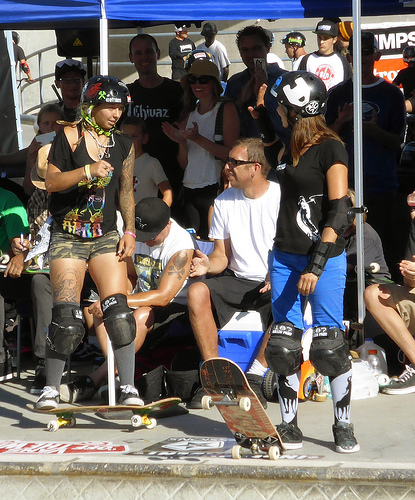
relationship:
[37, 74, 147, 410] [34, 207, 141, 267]
she wearing shorts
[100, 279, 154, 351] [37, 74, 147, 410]
knee pad on knees of she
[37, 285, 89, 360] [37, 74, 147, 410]
knee pad on knees of she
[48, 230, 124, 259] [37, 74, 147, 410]
camo shorts on she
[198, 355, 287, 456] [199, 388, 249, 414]
skateboard with wheels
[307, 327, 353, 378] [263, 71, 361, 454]
kneepad on girl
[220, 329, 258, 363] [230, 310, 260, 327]
cooler has white lid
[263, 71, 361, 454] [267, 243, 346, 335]
girl wearing pants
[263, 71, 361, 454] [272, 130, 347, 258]
girl wearing shirt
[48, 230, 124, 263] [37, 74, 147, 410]
camo shorts on a she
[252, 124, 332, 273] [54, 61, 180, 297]
shirt on woman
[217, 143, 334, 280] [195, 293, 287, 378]
he on cooler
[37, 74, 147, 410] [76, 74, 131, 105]
she wearing helmet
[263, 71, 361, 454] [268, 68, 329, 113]
girl wearing helmet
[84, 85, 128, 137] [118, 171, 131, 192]
she has tattoos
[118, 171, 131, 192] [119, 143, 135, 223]
tattoos on arm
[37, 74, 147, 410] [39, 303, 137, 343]
she wearing knee pads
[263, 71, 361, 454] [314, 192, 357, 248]
girl wearing pads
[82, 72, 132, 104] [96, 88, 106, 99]
helmet has sticker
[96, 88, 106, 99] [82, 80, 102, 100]
sticker has sticker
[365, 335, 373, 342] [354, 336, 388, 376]
blue lid on gallon jug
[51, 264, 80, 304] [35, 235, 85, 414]
tattoo on leg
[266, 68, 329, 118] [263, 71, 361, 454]
helmet on girl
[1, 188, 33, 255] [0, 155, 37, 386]
shirt on person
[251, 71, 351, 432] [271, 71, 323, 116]
girl wearing helmet